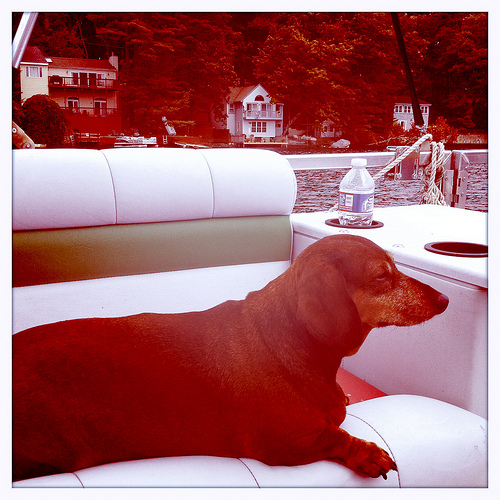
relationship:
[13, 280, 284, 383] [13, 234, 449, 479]
dog's back of dog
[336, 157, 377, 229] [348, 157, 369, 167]
bottle has top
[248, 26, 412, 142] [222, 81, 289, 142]
trees beside house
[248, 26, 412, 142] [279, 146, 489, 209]
trees beside lake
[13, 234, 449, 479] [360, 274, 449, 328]
dog has muzzle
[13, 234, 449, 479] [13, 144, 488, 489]
dog sitting on seat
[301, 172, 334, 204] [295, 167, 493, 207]
wave in water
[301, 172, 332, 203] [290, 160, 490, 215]
wave in water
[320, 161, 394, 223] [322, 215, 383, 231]
bottle in cup holder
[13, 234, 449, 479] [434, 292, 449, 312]
dog has nose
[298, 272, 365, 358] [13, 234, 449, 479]
ear of dog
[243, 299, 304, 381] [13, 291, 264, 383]
wrinkle on dog's back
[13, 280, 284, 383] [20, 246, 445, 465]
dog's back of a dog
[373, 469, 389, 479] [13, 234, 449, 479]
claw of a dog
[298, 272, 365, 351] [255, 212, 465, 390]
ear of a dog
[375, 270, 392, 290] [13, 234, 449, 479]
dog eye on dog